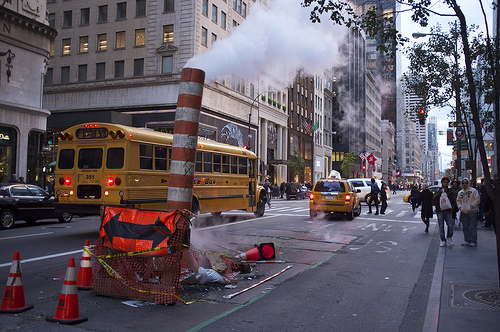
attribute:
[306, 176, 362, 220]
car — small, yellow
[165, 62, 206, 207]
cylinder — orange, white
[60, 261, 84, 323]
cone — caution cone, orange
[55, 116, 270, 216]
bus — yellow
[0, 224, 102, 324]
cones — orange, caution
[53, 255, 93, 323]
cone — orange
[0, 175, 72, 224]
car — black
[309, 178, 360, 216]
taxi — orange, stopped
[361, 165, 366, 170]
light — red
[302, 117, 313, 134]
flag — us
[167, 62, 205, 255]
object — orange, white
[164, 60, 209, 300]
object — tall, orange, white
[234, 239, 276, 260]
traffic cones — knocked over